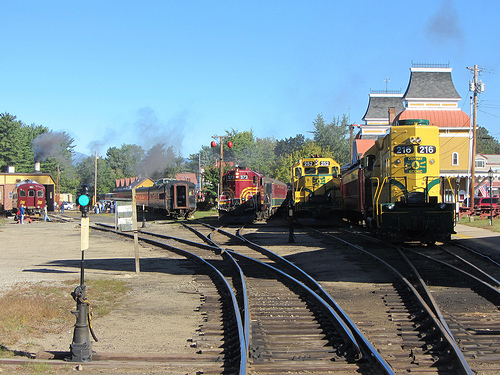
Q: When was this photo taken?
A: Outside, during the daytime.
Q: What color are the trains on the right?
A: Yellow.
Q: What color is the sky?
A: Blue.